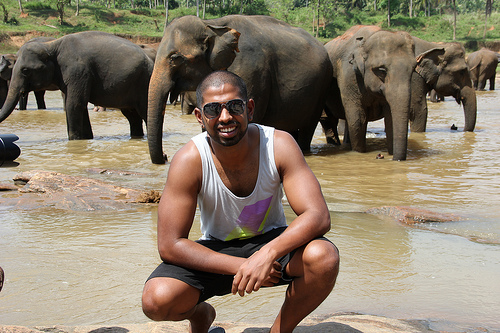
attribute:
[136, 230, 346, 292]
shorts — black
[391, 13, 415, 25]
leaves — green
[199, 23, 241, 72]
ear — big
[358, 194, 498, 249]
rocks — large, brown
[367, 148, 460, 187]
water — brown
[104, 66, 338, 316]
man — squatting down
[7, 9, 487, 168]
elephants — four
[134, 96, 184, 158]
trunk — brown, grey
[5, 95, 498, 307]
water — brown, cloudy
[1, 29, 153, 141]
elephant — black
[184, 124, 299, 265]
tank top — white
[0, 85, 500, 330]
water — brown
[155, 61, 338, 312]
man — squatting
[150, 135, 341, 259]
vest — white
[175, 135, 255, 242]
tank top — white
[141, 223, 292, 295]
shorts — black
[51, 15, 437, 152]
elephants — asian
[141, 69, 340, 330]
man — young, squatting, light skinned